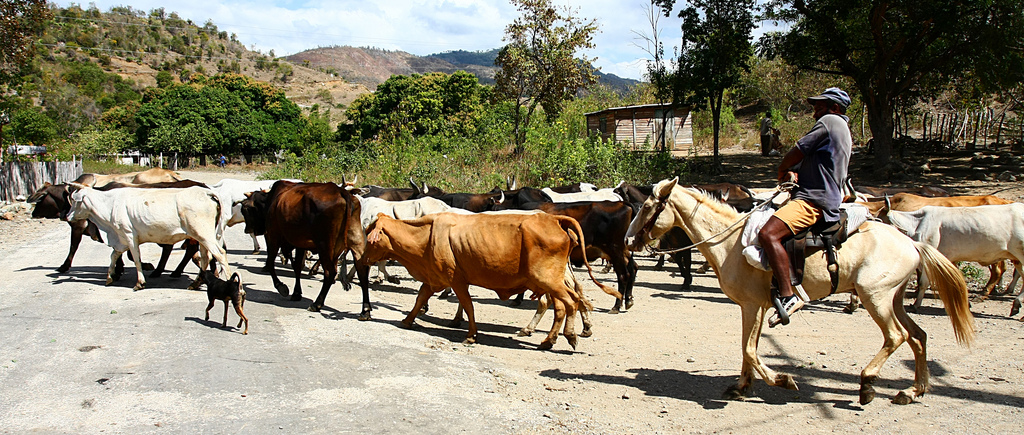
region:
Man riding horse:
[611, 54, 1017, 416]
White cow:
[71, 174, 253, 305]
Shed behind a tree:
[576, 82, 726, 177]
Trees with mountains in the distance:
[155, 4, 484, 156]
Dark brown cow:
[242, 159, 394, 328]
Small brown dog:
[185, 249, 277, 370]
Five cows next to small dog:
[21, 129, 377, 354]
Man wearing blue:
[217, 152, 225, 171]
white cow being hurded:
[63, 181, 231, 295]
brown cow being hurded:
[239, 181, 364, 308]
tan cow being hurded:
[359, 206, 623, 353]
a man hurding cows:
[758, 86, 850, 328]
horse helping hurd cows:
[628, 178, 979, 409]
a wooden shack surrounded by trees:
[581, 99, 700, 166]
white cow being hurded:
[882, 203, 1022, 302]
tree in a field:
[490, 3, 601, 156]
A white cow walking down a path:
[63, 186, 231, 292]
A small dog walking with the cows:
[196, 269, 250, 334]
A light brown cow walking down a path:
[360, 212, 618, 353]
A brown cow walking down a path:
[243, 181, 376, 317]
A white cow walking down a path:
[884, 196, 1022, 318]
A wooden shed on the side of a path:
[582, 101, 700, 158]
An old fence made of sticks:
[890, 108, 1020, 146]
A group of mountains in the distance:
[288, 47, 647, 101]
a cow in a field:
[877, 200, 1021, 311]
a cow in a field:
[511, 172, 630, 205]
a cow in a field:
[354, 197, 610, 340]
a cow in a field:
[352, 182, 458, 224]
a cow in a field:
[238, 177, 379, 315]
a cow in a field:
[61, 177, 236, 279]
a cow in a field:
[53, 149, 180, 197]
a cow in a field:
[236, 162, 372, 305]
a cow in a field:
[356, 204, 601, 353]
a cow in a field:
[511, 175, 648, 309]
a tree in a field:
[649, 9, 754, 158]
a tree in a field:
[502, 3, 602, 136]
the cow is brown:
[329, 194, 625, 355]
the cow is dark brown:
[230, 175, 382, 327]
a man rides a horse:
[610, 69, 984, 416]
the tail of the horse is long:
[909, 227, 992, 357]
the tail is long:
[560, 206, 636, 323]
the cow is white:
[58, 175, 237, 293]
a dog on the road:
[185, 253, 261, 342]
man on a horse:
[758, 76, 858, 346]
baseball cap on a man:
[802, 78, 856, 111]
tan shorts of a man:
[771, 193, 825, 235]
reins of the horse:
[635, 179, 791, 266]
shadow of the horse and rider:
[536, 347, 913, 423]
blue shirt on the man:
[786, 108, 854, 223]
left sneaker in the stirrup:
[773, 285, 805, 328]